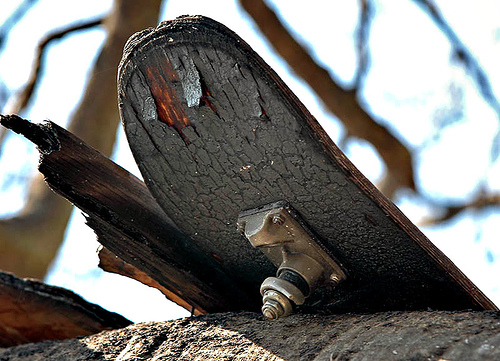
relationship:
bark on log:
[26, 108, 127, 270] [50, 310, 499, 357]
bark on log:
[0, 268, 136, 346] [50, 310, 499, 357]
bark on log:
[1, 312, 499, 359] [1, 314, 498, 359]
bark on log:
[1, 309, 498, 361] [74, 325, 475, 357]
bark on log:
[1, 309, 498, 361] [84, 303, 484, 358]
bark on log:
[0, 268, 138, 346] [1, 314, 498, 359]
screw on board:
[260, 276, 320, 323] [5, 13, 492, 320]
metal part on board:
[236, 199, 352, 316] [115, 13, 500, 321]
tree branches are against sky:
[2, 2, 499, 254] [2, 0, 498, 320]